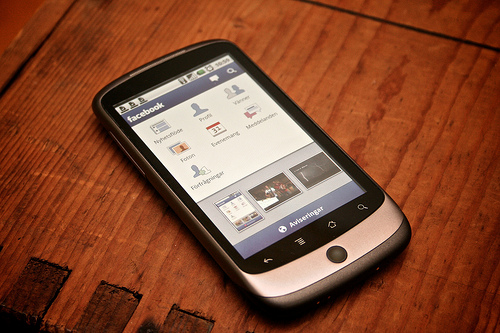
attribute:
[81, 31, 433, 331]
cell phone — silver, black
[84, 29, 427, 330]
phone — cell, on, silver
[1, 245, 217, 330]
marks — dark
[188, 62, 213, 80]
symbol — green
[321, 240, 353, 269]
button — black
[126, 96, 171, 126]
logo — white, blue, Facebook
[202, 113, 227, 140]
icon — white, red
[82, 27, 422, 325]
mobile phone — silver, black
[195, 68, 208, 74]
battery indicator — green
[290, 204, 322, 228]
aviseringar — logo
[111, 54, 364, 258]
image — webpage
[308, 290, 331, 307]
holes — Auxilliary jacks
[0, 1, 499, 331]
wood — scratched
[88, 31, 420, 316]
cell phone — opened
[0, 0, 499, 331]
table — wood, brown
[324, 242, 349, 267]
circle — dark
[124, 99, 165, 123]
letters — white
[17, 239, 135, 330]
strip — wooden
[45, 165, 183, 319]
table — edge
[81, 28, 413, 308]
phone screen — black framed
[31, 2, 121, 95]
spot — dark